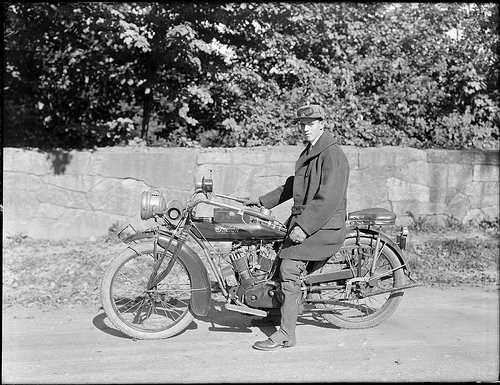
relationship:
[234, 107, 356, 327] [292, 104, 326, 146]
man has head